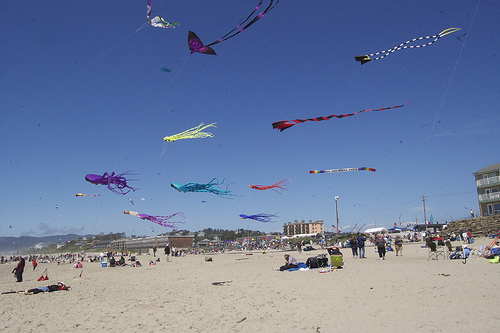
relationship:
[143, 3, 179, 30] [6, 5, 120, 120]
kite in sky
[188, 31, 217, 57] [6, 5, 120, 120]
kite in sky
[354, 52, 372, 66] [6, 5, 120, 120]
kite in sky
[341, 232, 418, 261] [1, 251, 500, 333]
people on sand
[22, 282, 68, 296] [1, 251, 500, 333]
person lying in sand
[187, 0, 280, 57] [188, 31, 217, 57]
butterfly shaped kite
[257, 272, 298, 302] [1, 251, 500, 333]
tan colored sand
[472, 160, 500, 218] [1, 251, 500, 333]
house near sand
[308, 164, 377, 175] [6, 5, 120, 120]
banner in sky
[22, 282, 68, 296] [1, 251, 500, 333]
person in sand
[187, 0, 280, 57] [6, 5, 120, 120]
butterfly in sky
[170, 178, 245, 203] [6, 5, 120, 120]
kite in sky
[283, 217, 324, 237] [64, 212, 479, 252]
building in background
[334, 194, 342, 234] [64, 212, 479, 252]
pole in background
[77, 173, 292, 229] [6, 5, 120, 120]
kites in sky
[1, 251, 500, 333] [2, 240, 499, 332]
sand on beach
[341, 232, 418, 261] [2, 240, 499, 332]
people on beach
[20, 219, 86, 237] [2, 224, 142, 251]
clouds in distance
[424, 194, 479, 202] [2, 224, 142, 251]
power line in distance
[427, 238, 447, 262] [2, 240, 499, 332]
chair on beach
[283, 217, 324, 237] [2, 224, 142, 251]
building in distance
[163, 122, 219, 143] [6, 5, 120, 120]
kite in sky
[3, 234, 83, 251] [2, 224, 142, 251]
mountain in distance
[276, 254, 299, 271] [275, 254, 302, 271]
body of man